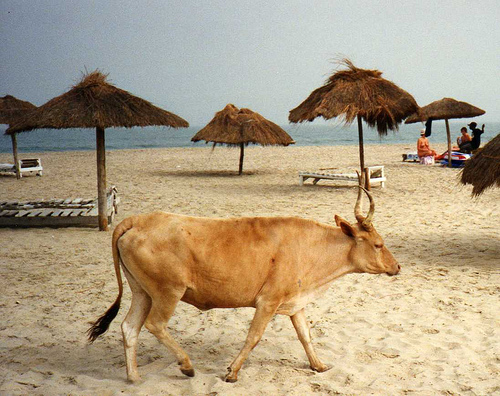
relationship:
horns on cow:
[339, 164, 412, 237] [99, 212, 395, 389]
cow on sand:
[82, 169, 402, 386] [54, 305, 426, 376]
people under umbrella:
[396, 123, 476, 176] [402, 90, 470, 125]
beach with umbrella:
[67, 140, 340, 231] [162, 68, 485, 174]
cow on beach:
[82, 169, 402, 386] [5, 275, 450, 392]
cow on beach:
[82, 169, 402, 386] [65, 166, 451, 368]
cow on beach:
[82, 169, 402, 386] [5, 150, 434, 390]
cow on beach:
[82, 169, 402, 386] [32, 126, 398, 267]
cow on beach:
[107, 190, 378, 380] [37, 141, 426, 392]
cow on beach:
[82, 169, 402, 386] [51, 150, 425, 382]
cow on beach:
[82, 169, 402, 386] [28, 270, 384, 390]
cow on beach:
[82, 169, 402, 386] [29, 158, 478, 388]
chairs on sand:
[6, 159, 108, 282] [16, 206, 101, 311]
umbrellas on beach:
[181, 74, 287, 194] [173, 142, 272, 225]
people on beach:
[381, 80, 480, 213] [396, 170, 496, 252]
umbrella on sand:
[440, 126, 493, 191] [425, 214, 489, 314]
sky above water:
[175, 42, 258, 118] [255, 93, 323, 160]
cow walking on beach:
[82, 169, 402, 386] [313, 298, 446, 391]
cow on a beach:
[82, 169, 402, 386] [160, 99, 350, 184]